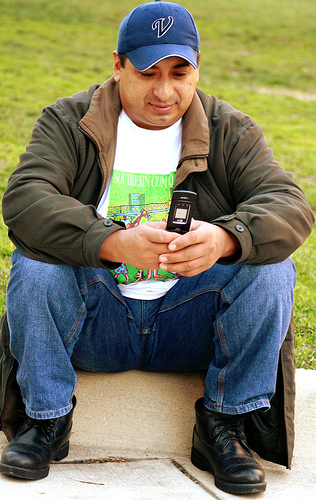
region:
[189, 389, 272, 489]
Black boot on mans foot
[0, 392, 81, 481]
Black boot on mans foot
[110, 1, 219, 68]
White and blue hat on man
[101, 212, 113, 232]
Small button on mans sleve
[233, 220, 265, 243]
Small button on mans sleve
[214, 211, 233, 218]
Small button on mans sleve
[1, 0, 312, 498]
a person sitting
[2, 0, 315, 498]
a person holding his cellphone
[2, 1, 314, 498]
a person looking at his phone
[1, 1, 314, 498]
a person wearing blue jeans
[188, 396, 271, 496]
black shoe person is wearing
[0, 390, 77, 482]
black shoe the person is wearing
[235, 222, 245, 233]
a button on the coat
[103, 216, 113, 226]
a button on the coat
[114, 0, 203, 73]
a hat the person is wearing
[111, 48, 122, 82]
an ear of the person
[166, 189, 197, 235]
the black cell phone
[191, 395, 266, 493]
the black shiny boot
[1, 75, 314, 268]
the button on the jacket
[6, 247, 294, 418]
the blue jeans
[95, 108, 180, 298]
the white shirt with a design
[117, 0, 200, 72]
the design on the hat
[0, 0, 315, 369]
the green grass on the ground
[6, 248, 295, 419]
the stiching on the jeans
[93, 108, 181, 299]
the design on the white shirt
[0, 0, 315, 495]
person is sitting and holding a phone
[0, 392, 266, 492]
person is wearing black boots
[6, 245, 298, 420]
person is wearing blue jeans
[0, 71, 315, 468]
coat is brown and tan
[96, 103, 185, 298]
shirt is white with print on it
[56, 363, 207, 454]
stone block is white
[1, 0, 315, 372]
grass is green and uncut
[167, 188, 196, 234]
cell phone is black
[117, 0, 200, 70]
person has blue baseball hat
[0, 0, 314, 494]
Man looking at his cell phone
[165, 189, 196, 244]
Black cell phone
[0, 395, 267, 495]
Black boots on man's feet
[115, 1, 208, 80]
baseball cap with logo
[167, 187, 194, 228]
small black cell phone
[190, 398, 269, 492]
shiny black shoe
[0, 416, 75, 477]
shiny black shoe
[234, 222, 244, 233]
brown button on jacket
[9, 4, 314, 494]
a man wearing a blue cap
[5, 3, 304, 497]
a man wearing a long brown coat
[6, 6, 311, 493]
a man holding a cell phone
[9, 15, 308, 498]
a man wearing a white t shirt with green picture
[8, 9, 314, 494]
a man sitting on the curb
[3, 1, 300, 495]
a man looking at a cell phone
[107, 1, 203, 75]
a blue hat with a V on it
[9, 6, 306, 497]
a man wearing black shoes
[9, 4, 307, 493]
a man wearing jeans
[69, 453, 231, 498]
a crack in the concrete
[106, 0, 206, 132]
Blue hat on man's head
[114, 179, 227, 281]
A cell phone in two hands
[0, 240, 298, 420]
A pair of blue jeans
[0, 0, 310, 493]
A man sitting on a step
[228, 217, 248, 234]
A tiny round button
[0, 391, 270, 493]
A pair of black boots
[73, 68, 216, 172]
Brown collar of a jacket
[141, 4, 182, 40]
"V" written on blue hat